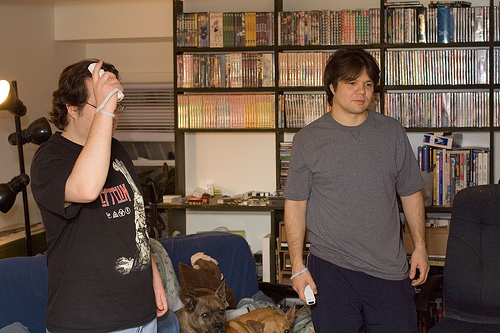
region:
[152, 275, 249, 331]
Dog in the room.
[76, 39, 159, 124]
Playing WII with friends.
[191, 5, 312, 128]
Media storage shelf in room.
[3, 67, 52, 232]
Lighting for room.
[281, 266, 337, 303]
Wii controller.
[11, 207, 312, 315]
Couch with dogs watching the WII being played.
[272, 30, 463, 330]
Man waiting for his turn to play Wii.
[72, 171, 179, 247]
Black t-shirt on man playing Wii.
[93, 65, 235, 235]
Window with blind in it.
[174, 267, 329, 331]
Two dogs on the couch.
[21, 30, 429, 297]
men standing while playing an electronic game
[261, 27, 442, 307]
grey shirt with hem slanted across waist and hip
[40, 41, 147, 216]
man standing with raised arm holding remote control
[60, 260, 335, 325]
dog with black eyes between both men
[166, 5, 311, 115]
rows of books with their spines facing outward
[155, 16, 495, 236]
large and filled bookcase occupying much space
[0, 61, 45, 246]
standing lamp with three light fixtures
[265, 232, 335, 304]
remote control held in curled hand with strap around wrist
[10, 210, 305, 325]
blue sofa behind player with dog and clothes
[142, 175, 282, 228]
cluttered shelf filled with little objects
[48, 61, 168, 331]
man in a black t shirt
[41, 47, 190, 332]
man holding a wii controller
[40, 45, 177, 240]
man with brown hair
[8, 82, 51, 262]
black free standing lamp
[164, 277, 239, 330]
Dog laying on a couch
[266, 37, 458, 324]
Man in a gray t-shirt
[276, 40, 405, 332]
man in dark blue sweats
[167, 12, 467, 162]
Book shelf on a wall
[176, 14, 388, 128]
DVDs on a book shelf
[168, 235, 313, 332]
two dogs on a couch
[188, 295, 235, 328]
a pretty dog is on the image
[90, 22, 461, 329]
they are inside a house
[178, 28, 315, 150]
books are on the shelf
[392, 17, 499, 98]
neatly arranged books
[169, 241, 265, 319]
this is a couch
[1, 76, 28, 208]
there are lights on the back ground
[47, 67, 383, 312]
two guys are on the image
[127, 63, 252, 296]
the image was taken at night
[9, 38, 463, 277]
the room looks neat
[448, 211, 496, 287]
a chair is on the image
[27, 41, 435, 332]
Two men playing Wii.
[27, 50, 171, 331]
Man in a black t-shirt with a Wii controller.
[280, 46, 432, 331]
Man in a grey t-shirt with a Wii controller.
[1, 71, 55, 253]
Black lamp with 3 lights.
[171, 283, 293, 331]
Two dogs, relaxing.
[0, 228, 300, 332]
Blue sofa with two dogs laying on it.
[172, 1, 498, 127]
Full book shelves.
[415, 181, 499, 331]
Black desk chair.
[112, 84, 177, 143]
White blinds.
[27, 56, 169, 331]
Man holding Wii controller by his face.